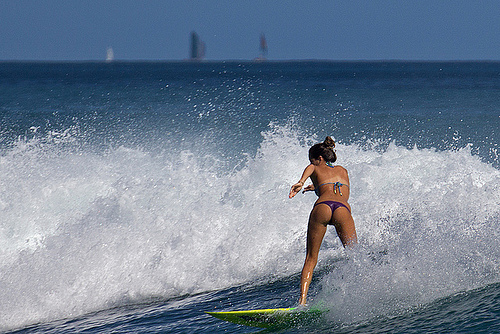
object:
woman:
[287, 135, 362, 309]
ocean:
[0, 59, 500, 334]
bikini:
[312, 161, 351, 226]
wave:
[0, 128, 500, 334]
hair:
[308, 136, 337, 164]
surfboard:
[199, 303, 332, 332]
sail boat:
[103, 44, 115, 64]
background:
[4, 0, 499, 119]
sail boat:
[182, 30, 208, 63]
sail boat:
[250, 30, 271, 62]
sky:
[0, 0, 498, 64]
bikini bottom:
[312, 200, 352, 226]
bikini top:
[313, 161, 350, 197]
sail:
[188, 30, 206, 59]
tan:
[314, 165, 349, 183]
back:
[313, 165, 351, 205]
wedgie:
[330, 205, 336, 225]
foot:
[297, 299, 307, 308]